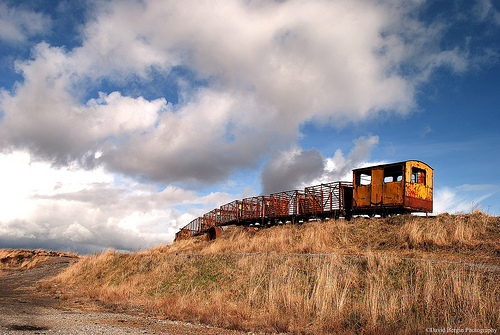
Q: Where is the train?
A: On a hill.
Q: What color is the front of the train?
A: Yellow.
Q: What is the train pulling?
A: Cages.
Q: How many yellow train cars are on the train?
A: 1.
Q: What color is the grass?
A: Tan.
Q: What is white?
A: Clouds.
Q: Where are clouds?
A: In the sky.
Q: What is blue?
A: Sky.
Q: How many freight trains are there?
A: One.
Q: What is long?
A: Grass.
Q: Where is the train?
A: On tracks.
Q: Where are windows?
A: On the train.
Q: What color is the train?
A: Yellow.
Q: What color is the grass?
A: Green and yellow.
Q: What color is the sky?
A: Blue.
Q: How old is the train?
A: Very old.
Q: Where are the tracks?
A: On a hill.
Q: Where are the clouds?
A: In the sky.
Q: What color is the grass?
A: Brown.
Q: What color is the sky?
A: Blue.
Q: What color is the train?
A: Brown.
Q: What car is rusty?
A: The last one.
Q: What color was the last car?
A: Yellow.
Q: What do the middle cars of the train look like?
A: Cages.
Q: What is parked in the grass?
A: An old train.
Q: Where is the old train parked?
A: In the grass.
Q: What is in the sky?
A: Clouds.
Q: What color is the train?
A: Yellow and rust.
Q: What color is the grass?
A: Brown.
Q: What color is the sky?
A: Bright blue.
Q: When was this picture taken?
A: In the daytime.